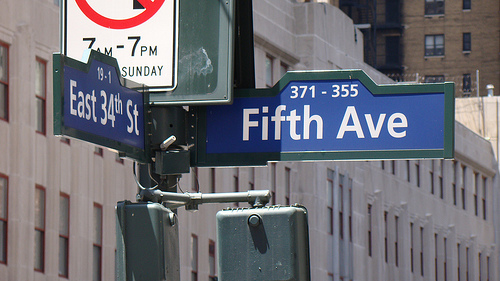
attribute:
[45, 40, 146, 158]
sign — blue , white 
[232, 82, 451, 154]
sign — blue 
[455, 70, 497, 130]
sign — street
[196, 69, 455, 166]
street sign — blue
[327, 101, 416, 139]
print — white 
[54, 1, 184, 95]
sign — white, red, black 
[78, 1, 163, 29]
circle — red 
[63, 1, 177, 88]
background — white 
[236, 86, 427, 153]
sign — blue , white 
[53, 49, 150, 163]
sign — street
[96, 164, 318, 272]
boxes — black 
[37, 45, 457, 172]
signs — blue 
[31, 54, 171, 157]
sign — black, frame, blue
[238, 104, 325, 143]
print — white 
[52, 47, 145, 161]
street sign — blue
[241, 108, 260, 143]
letter — white 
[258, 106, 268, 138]
letter — white 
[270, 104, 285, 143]
letter — white 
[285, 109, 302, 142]
letter — white 